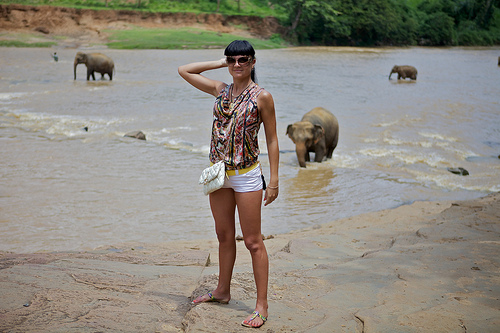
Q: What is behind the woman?
A: A stream.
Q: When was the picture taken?
A: Daytime.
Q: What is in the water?
A: Elephants.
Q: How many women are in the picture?
A: One.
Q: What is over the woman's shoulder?
A: A purse.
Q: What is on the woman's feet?
A: Sandals.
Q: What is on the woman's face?
A: Glasses.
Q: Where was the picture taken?
A: On a riverbank.